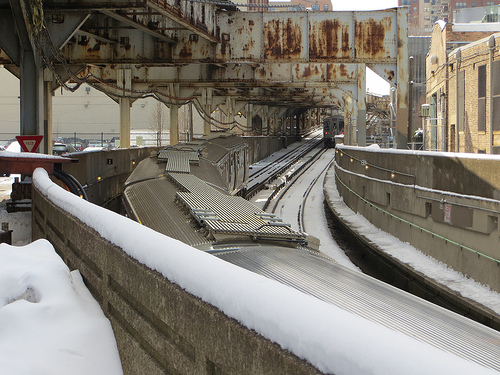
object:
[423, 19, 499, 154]
building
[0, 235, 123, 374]
snow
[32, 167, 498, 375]
wall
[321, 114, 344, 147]
train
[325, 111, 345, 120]
top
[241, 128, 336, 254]
tracks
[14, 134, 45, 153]
sign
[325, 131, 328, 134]
lights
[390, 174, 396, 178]
lights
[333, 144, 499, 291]
wall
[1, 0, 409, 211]
overpass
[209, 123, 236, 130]
wires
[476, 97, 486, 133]
windows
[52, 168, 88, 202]
cables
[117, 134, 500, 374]
train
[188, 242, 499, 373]
top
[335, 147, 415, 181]
hand rail